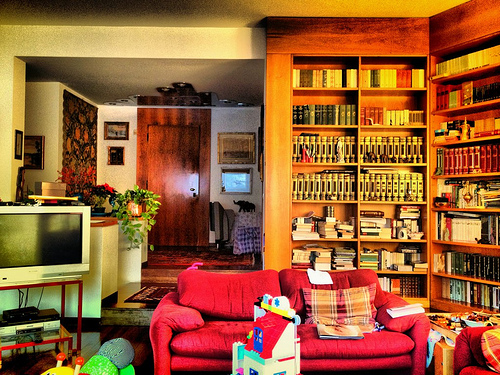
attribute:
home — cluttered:
[1, 2, 497, 372]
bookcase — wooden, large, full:
[263, 2, 498, 314]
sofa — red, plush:
[150, 269, 430, 373]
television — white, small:
[0, 204, 92, 286]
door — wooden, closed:
[147, 126, 198, 246]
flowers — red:
[60, 167, 97, 185]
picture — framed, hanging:
[104, 121, 130, 141]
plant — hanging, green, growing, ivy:
[114, 185, 161, 250]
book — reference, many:
[294, 105, 298, 125]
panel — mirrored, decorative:
[173, 81, 195, 96]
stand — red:
[1, 282, 84, 365]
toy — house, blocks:
[234, 292, 300, 374]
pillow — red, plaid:
[302, 284, 378, 326]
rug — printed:
[124, 281, 179, 302]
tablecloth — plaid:
[234, 212, 261, 252]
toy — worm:
[42, 337, 137, 375]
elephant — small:
[235, 200, 257, 213]